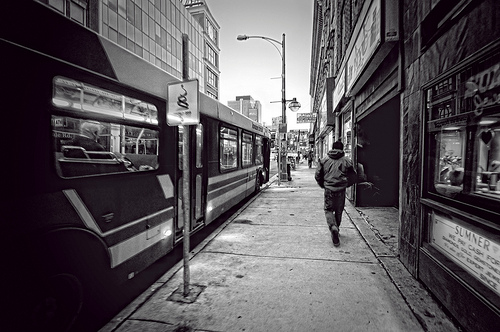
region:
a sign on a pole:
[115, 64, 225, 172]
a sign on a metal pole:
[154, 58, 200, 143]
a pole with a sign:
[157, 46, 221, 143]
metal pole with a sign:
[151, 53, 221, 142]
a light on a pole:
[225, 16, 315, 98]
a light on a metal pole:
[247, 16, 291, 83]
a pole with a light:
[228, 16, 289, 71]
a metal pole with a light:
[218, 15, 296, 83]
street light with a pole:
[229, 11, 307, 108]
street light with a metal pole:
[239, 23, 289, 77]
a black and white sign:
[154, 65, 220, 135]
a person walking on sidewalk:
[295, 105, 405, 242]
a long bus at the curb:
[43, 18, 293, 269]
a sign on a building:
[303, 19, 433, 104]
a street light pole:
[227, 22, 310, 211]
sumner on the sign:
[443, 217, 498, 264]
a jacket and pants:
[307, 129, 375, 266]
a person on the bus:
[57, 117, 155, 182]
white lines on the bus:
[106, 150, 274, 268]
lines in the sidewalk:
[196, 166, 395, 293]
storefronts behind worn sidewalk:
[307, 5, 497, 307]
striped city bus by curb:
[0, 10, 275, 320]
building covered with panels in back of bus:
[56, 1, 218, 96]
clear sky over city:
[205, 0, 311, 130]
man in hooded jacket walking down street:
[310, 135, 355, 245]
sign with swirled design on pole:
[165, 25, 200, 300]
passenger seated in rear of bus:
[65, 120, 125, 165]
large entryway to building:
[341, 85, 426, 245]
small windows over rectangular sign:
[425, 110, 495, 295]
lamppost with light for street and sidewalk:
[235, 25, 303, 185]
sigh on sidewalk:
[164, 71, 219, 304]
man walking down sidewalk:
[305, 130, 363, 266]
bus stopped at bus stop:
[152, 85, 279, 240]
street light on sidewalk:
[233, 21, 308, 193]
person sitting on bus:
[61, 118, 127, 165]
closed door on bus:
[177, 128, 219, 230]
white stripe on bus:
[92, 198, 193, 258]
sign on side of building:
[424, 207, 498, 280]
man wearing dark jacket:
[313, 140, 370, 192]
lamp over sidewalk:
[284, 91, 309, 116]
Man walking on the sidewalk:
[314, 129, 359, 249]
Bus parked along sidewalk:
[6, 6, 273, 243]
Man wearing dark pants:
[319, 183, 347, 234]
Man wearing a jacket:
[309, 150, 363, 190]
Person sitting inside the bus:
[72, 117, 107, 153]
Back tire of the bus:
[32, 227, 120, 327]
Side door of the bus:
[172, 95, 217, 239]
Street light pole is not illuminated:
[233, 20, 298, 187]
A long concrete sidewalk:
[195, 155, 345, 330]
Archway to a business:
[342, 96, 410, 238]